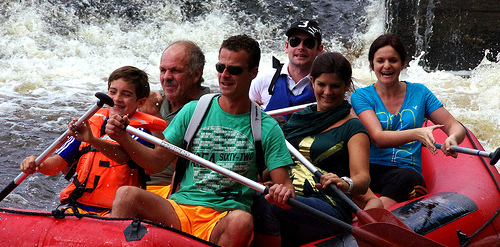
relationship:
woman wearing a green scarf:
[278, 55, 376, 227] [283, 103, 359, 139]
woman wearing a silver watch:
[278, 55, 376, 227] [340, 174, 360, 194]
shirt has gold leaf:
[279, 110, 371, 220] [287, 135, 351, 208]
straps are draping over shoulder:
[182, 94, 277, 164] [240, 106, 297, 178]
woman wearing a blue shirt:
[355, 33, 469, 185] [355, 85, 446, 176]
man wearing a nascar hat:
[260, 16, 321, 109] [283, 15, 326, 49]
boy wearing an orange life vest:
[52, 63, 171, 218] [71, 108, 163, 204]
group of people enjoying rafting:
[71, 18, 465, 240] [5, 3, 499, 246]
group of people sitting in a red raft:
[71, 18, 465, 240] [0, 133, 500, 246]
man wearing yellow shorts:
[117, 34, 295, 244] [161, 195, 254, 246]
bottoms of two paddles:
[345, 206, 452, 245] [127, 118, 455, 246]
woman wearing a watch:
[278, 55, 376, 227] [340, 174, 360, 194]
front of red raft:
[4, 204, 218, 245] [0, 133, 500, 246]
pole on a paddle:
[114, 124, 357, 237] [106, 120, 448, 246]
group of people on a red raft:
[71, 18, 465, 240] [0, 133, 500, 246]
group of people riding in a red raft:
[71, 18, 465, 240] [0, 133, 500, 246]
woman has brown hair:
[278, 55, 376, 227] [307, 50, 357, 95]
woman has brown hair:
[355, 33, 469, 185] [365, 31, 411, 71]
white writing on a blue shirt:
[389, 149, 416, 164] [355, 85, 446, 176]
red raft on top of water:
[0, 133, 500, 246] [4, 4, 63, 173]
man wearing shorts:
[117, 34, 295, 244] [161, 195, 254, 246]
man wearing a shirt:
[117, 34, 295, 244] [162, 96, 295, 202]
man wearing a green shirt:
[117, 34, 295, 244] [162, 96, 295, 202]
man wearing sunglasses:
[260, 16, 321, 109] [287, 36, 323, 51]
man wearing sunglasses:
[117, 34, 295, 244] [211, 61, 259, 78]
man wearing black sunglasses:
[260, 16, 321, 109] [287, 36, 323, 51]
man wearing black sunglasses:
[117, 34, 295, 244] [211, 61, 259, 78]